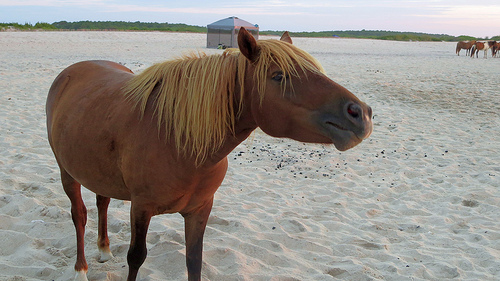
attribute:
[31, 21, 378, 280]
pony — brown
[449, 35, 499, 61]
horses — standing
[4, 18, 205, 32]
trees — green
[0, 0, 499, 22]
sky — blue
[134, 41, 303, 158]
mane — blond, brown, blonde, yellow, straight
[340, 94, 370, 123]
nose — dark brown, dark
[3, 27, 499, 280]
sand — tan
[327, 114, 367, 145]
mouth — black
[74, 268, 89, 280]
hair — white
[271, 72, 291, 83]
eye — brown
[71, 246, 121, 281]
feet — white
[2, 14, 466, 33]
hill — green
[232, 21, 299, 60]
ears — ponty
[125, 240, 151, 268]
knee — dark